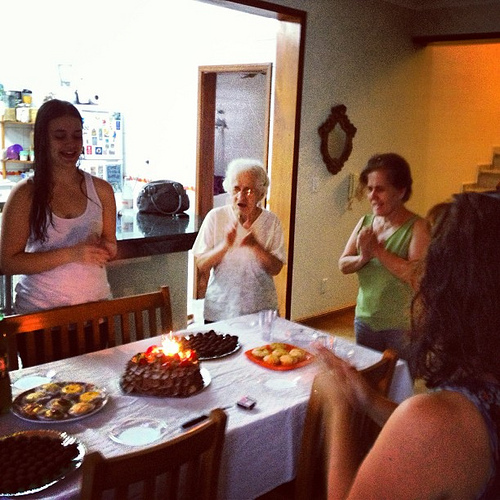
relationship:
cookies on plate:
[243, 338, 312, 379] [272, 364, 292, 377]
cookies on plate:
[205, 336, 237, 369] [230, 340, 242, 361]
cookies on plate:
[25, 434, 63, 494] [38, 432, 91, 457]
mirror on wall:
[311, 106, 356, 159] [335, 40, 380, 91]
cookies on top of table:
[251, 347, 269, 356] [217, 364, 270, 402]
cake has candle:
[134, 357, 204, 400] [168, 331, 173, 355]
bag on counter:
[142, 171, 189, 205] [140, 211, 177, 238]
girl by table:
[28, 111, 94, 375] [217, 364, 270, 402]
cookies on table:
[243, 338, 312, 379] [217, 364, 270, 402]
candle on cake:
[168, 331, 173, 355] [134, 357, 204, 400]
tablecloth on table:
[230, 423, 292, 498] [217, 364, 270, 402]